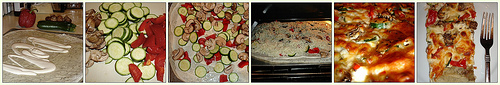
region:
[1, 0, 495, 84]
step by step photo on how to make pizza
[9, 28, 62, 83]
pizza dough with white sauce on it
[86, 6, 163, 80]
chopped vegetables in photo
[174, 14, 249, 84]
chopped vegetables on top of dough and sauch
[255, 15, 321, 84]
shredded cheese on top of chopped vegetables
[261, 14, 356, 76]
pizza dough with toppings in oven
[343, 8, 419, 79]
pizza cooking in oven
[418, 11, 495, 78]
slice of pizza ready to serve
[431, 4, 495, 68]
silver fork next to slice of pizza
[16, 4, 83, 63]
cucumber, mushrooms, and pepper behind dough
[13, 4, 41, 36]
A red pepper on the table.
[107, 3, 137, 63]
Cut pieces of zuchinni.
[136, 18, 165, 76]
Cut up pieces of pepper.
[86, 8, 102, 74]
A pile of mushroom pieces.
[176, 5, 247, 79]
Veggies on the sauce.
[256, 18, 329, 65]
Baking dinner in the oven.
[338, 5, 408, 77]
Melted cheese on the top.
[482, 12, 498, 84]
A fork on the table.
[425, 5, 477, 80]
Dinner on the plate.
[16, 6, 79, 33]
A group of veggies.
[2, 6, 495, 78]
steps to making pizza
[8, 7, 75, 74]
putting sauce on pizza dough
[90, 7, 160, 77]
the toppings for pizza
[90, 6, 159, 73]
cucumber tomato and mushrooms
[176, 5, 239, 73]
putting the toppings on pizza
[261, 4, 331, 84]
baking pizza in oven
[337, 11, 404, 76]
freshly baked pizza cooling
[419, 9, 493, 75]
eating the slice of pizza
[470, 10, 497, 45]
the fork is silver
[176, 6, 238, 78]
spreading the toppings evenly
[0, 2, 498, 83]
The photo is a group of six photos.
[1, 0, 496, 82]
The photos are of food.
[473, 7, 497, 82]
A fork is in the last one.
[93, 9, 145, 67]
A pile of cucumbers.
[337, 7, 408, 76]
A cooked product.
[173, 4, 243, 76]
Different types of toppings.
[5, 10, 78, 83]
The first step is shown.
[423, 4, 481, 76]
The finished product.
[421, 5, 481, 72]
It is now ready to eat.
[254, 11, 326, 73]
How it looks before cooking.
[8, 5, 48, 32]
red food on the table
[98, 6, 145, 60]
green cucumbers on table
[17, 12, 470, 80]
many photos of food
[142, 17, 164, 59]
red food next to cucumbers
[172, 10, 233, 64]
many different food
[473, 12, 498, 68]
silver fork next to food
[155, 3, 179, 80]
white line between picture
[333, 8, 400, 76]
close up photo of food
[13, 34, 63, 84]
white sauce on surface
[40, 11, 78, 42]
green piece of food